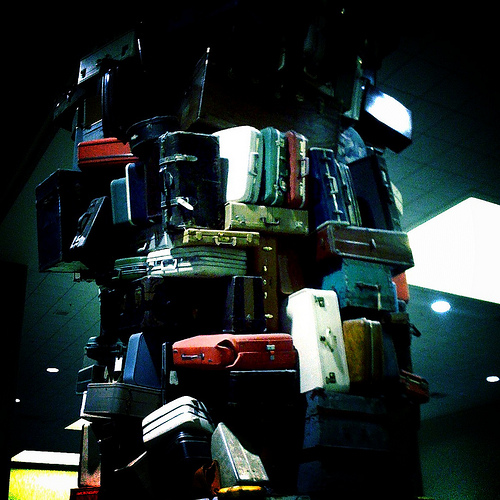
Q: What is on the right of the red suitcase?
A: A white suitcase.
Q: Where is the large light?
A: Ceiling.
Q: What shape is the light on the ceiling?
A: Square.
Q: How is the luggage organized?
A: Stacked.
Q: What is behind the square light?
A: A small round light.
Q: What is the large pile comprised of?
A: Suitcases.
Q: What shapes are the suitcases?
A: Rectangle.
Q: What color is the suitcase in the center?
A: Red.